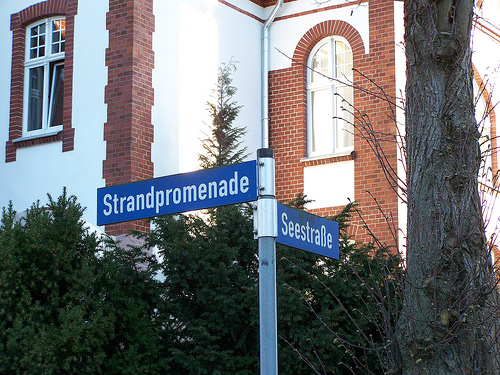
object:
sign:
[95, 160, 257, 228]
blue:
[295, 212, 299, 219]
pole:
[251, 147, 278, 374]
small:
[199, 55, 255, 169]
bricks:
[364, 173, 378, 179]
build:
[101, 0, 158, 237]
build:
[6, 1, 81, 163]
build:
[470, 62, 500, 188]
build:
[217, 0, 369, 27]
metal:
[261, 316, 278, 363]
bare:
[469, 0, 500, 267]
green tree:
[203, 50, 254, 246]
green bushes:
[0, 186, 404, 374]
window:
[28, 67, 43, 130]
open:
[46, 61, 66, 130]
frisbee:
[58, 65, 66, 87]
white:
[59, 69, 65, 77]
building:
[0, 0, 500, 348]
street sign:
[276, 202, 341, 262]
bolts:
[256, 157, 275, 199]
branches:
[272, 44, 405, 111]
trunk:
[394, 0, 499, 374]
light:
[177, 0, 220, 226]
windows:
[310, 84, 335, 154]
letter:
[320, 224, 326, 247]